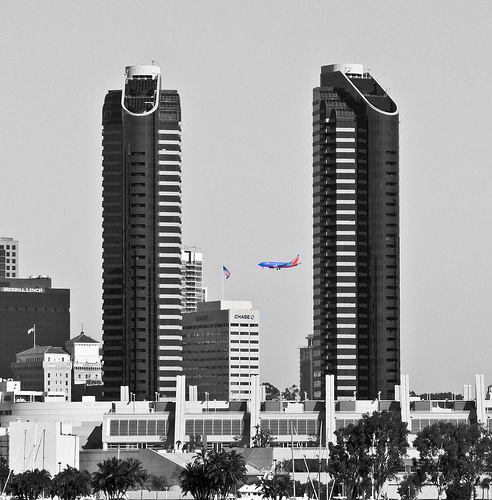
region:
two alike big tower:
[53, 39, 417, 395]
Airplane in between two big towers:
[81, 77, 431, 383]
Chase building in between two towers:
[179, 260, 269, 411]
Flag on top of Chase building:
[182, 232, 271, 389]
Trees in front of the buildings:
[27, 419, 455, 497]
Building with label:
[0, 238, 119, 338]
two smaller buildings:
[2, 315, 100, 393]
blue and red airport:
[253, 247, 304, 279]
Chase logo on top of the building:
[218, 304, 255, 336]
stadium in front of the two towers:
[36, 368, 479, 450]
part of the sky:
[214, 15, 261, 86]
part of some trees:
[204, 454, 231, 482]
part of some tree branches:
[429, 465, 450, 493]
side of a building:
[317, 295, 356, 356]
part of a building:
[170, 383, 184, 410]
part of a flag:
[24, 326, 34, 336]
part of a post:
[29, 328, 40, 345]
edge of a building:
[220, 348, 236, 377]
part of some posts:
[280, 442, 322, 492]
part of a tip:
[73, 314, 86, 337]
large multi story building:
[111, 63, 186, 391]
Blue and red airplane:
[254, 254, 301, 272]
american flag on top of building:
[216, 266, 232, 300]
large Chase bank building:
[188, 302, 262, 406]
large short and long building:
[12, 398, 489, 492]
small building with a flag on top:
[20, 323, 72, 408]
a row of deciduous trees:
[340, 416, 476, 498]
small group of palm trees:
[183, 453, 249, 494]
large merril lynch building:
[1, 286, 71, 362]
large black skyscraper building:
[320, 65, 400, 405]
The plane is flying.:
[240, 238, 325, 280]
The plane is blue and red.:
[252, 246, 314, 274]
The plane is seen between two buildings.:
[78, 51, 437, 403]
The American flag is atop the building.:
[212, 255, 238, 303]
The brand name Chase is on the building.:
[224, 309, 263, 323]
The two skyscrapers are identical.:
[82, 43, 424, 398]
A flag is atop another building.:
[17, 318, 43, 351]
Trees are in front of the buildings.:
[0, 432, 264, 497]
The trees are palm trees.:
[0, 432, 264, 498]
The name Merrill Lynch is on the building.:
[0, 279, 52, 304]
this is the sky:
[192, 10, 263, 106]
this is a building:
[311, 57, 400, 387]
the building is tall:
[313, 62, 396, 374]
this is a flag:
[219, 263, 230, 292]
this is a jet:
[259, 255, 305, 271]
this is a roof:
[31, 343, 55, 353]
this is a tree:
[369, 412, 395, 492]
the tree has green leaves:
[374, 418, 390, 434]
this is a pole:
[290, 417, 296, 496]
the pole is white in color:
[289, 423, 293, 451]